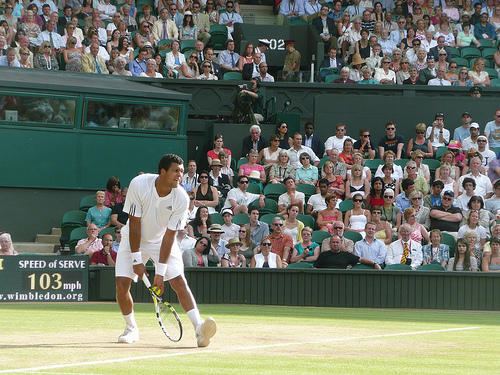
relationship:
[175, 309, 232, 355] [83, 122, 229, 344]
shoe of man